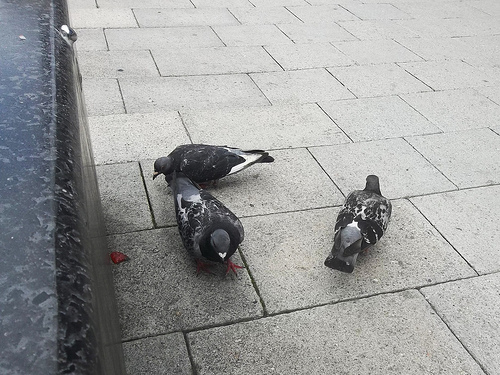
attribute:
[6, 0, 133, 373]
wall — smooth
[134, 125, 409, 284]
birds — black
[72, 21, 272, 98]
pavers — brick, patterned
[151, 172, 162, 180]
beak — black, white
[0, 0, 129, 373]
curb — black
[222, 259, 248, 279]
foot — small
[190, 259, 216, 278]
foot — small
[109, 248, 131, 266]
pedaql — red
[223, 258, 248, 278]
feet — orange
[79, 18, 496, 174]
floor — squared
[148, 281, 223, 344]
path — stone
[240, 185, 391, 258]
pigeons — three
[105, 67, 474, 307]
birds — small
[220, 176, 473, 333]
tile — concrete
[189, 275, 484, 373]
tile — concrete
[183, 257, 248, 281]
claws — black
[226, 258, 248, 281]
foot — red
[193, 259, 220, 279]
foot — red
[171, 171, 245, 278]
pigeon — gray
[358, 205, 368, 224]
stripes — white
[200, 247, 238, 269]
beak — white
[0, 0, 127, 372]
divider — black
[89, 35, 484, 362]
floor — brown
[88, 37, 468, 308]
slabs — rectangular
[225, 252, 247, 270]
leg — red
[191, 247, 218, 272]
leg — red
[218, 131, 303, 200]
tail — white, grey